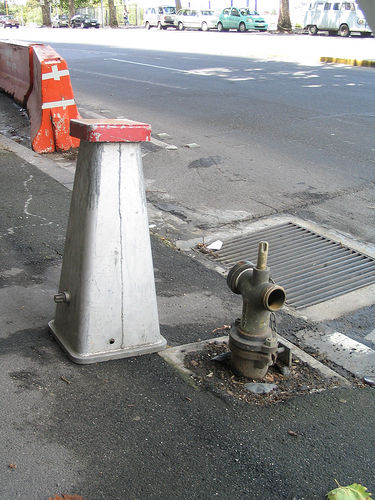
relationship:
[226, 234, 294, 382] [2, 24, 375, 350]
water hydrant near road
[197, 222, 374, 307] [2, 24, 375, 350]
storm grate in road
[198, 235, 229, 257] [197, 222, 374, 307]
garbage on top of storm grate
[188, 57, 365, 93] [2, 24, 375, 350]
shadows are on road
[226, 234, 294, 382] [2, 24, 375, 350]
water hydrant next to road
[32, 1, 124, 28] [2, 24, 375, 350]
trees are across road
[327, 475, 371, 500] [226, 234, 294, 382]
leaf near water hydrant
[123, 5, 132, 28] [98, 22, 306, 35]
person on sidewalk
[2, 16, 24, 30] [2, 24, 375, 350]
car driving on road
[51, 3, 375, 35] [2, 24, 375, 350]
six vehicles are parked on road